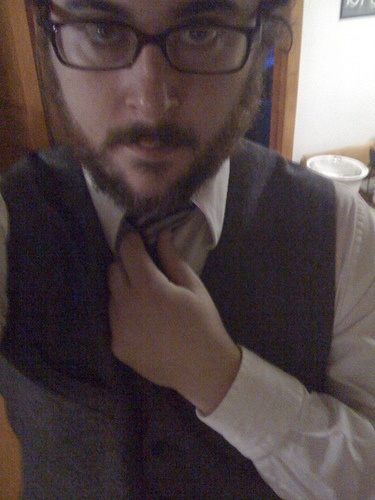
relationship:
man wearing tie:
[21, 8, 357, 498] [122, 199, 197, 267]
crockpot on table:
[301, 152, 371, 201] [302, 146, 374, 208]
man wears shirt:
[21, 8, 357, 498] [0, 150, 374, 498]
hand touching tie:
[104, 229, 227, 393] [126, 200, 196, 271]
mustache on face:
[105, 106, 199, 170] [49, 2, 254, 195]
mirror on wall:
[340, 0, 372, 20] [291, 0, 373, 165]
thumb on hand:
[153, 222, 204, 292] [108, 229, 219, 385]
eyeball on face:
[81, 19, 127, 46] [49, 2, 265, 195]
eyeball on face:
[180, 23, 219, 45] [49, 2, 265, 195]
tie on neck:
[122, 199, 194, 269] [97, 178, 214, 244]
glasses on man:
[51, 11, 238, 67] [48, 12, 326, 425]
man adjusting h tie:
[21, 8, 357, 498] [122, 205, 209, 498]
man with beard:
[21, 8, 357, 498] [90, 82, 232, 228]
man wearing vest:
[21, 8, 357, 498] [6, 137, 354, 499]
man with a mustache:
[21, 8, 357, 498] [105, 114, 199, 156]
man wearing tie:
[21, 8, 357, 498] [112, 201, 202, 332]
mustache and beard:
[105, 125, 196, 170] [41, 46, 264, 214]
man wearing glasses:
[21, 8, 357, 498] [26, 1, 272, 87]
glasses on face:
[51, 11, 259, 76] [49, 2, 265, 195]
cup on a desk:
[306, 153, 370, 192] [298, 141, 373, 209]